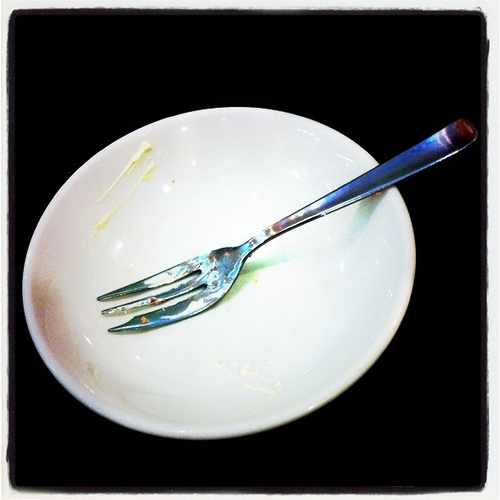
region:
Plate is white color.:
[35, 117, 366, 413]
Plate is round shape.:
[65, 112, 395, 424]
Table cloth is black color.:
[7, 12, 482, 487]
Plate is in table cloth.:
[15, 65, 441, 431]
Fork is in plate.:
[89, 196, 338, 373]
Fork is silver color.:
[106, 200, 337, 363]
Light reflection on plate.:
[72, 156, 423, 411]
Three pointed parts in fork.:
[93, 252, 216, 342]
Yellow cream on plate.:
[85, 131, 170, 241]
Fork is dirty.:
[119, 232, 241, 332]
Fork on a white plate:
[93, 198, 340, 353]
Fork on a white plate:
[103, 155, 429, 477]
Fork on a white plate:
[96, 254, 260, 329]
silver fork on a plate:
[90, 255, 265, 352]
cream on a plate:
[88, 153, 168, 223]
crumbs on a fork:
[128, 300, 172, 342]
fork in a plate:
[123, 190, 288, 332]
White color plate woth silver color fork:
[65, 155, 397, 420]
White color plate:
[291, 287, 396, 369]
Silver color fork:
[387, 115, 480, 182]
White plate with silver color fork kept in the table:
[30, 43, 459, 400]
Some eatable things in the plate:
[91, 139, 171, 236]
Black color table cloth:
[401, 350, 461, 455]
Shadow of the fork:
[231, 200, 398, 289]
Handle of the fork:
[426, 120, 481, 177]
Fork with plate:
[26, 140, 431, 430]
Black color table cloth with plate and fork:
[20, 44, 491, 496]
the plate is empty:
[37, 60, 483, 482]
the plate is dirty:
[23, 44, 464, 474]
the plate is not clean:
[7, 76, 494, 480]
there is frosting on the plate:
[27, 65, 489, 499]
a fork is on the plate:
[17, 73, 498, 452]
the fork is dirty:
[76, 110, 494, 340]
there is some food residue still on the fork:
[83, 218, 319, 362]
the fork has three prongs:
[82, 223, 253, 357]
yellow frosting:
[86, 135, 195, 250]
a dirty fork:
[87, 105, 489, 362]